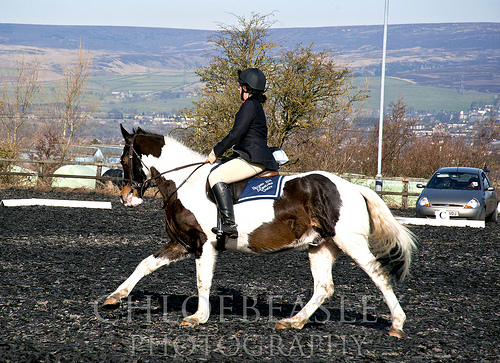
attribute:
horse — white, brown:
[104, 123, 418, 362]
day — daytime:
[4, 8, 498, 20]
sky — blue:
[68, 6, 181, 28]